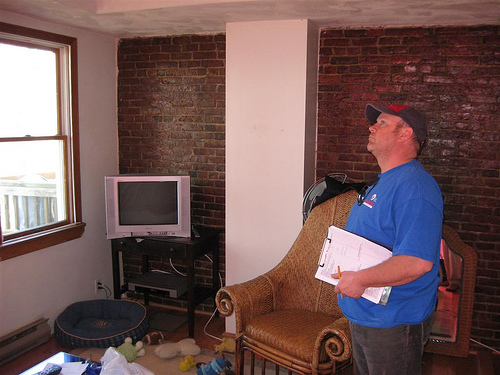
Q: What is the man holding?
A: A pen and clipboard.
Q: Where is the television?
A: On the stand.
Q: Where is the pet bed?
A: Next to the tv stand.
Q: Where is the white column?
A: Next to the wall.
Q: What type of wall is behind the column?
A: A brick wall.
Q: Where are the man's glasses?
A: On his shirt.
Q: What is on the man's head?
A: A cap.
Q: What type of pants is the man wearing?
A: Black jeans.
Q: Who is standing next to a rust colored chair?
A: A man.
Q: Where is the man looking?
A: Ceiling.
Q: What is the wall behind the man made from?
A: Bricks.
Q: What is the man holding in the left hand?
A: Clipboard.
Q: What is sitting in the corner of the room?
A: Television.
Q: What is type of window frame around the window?
A: Wooden.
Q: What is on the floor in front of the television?
A: Game controllers.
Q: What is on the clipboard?
A: Papers.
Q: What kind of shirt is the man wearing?
A: Blue T-shirt.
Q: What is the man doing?
A: Looking at the ceiling.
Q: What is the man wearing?
A: A blue shirt and grey pants.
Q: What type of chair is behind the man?
A: Tight-weaved rattan.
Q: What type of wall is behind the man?
A: Brick wall.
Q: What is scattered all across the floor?
A: Kids' toys.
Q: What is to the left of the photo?
A: The window.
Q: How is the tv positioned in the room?
A: In the corner.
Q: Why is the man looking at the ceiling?
A: Inspection.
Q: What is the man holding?
A: A clipboard.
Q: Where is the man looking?
A: At the ceiling.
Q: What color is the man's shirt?
A: Blue.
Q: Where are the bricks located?
A: The wall.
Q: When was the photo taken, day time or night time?
A: Daytime.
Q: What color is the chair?
A: Brown.